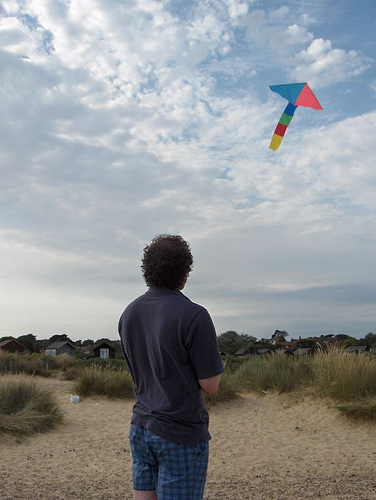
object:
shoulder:
[177, 296, 209, 327]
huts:
[36, 337, 366, 355]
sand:
[0, 401, 376, 500]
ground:
[0, 399, 376, 500]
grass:
[1, 345, 375, 437]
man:
[118, 233, 222, 500]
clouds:
[10, 10, 374, 179]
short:
[129, 424, 209, 500]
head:
[141, 234, 193, 289]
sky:
[2, 2, 372, 343]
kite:
[269, 82, 324, 150]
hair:
[141, 234, 193, 290]